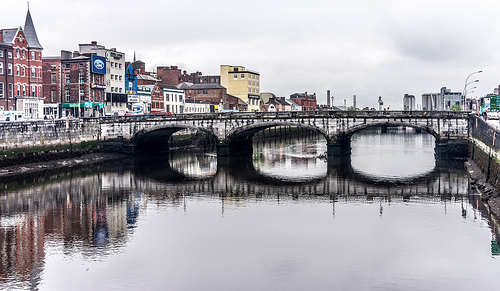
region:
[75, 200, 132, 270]
reflection in the water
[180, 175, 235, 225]
water next to the bridge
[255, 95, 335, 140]
bridge above the water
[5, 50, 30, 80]
windows on the building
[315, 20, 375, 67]
white sky above bridge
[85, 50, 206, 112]
many buildings next to bridge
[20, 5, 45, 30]
top of the tower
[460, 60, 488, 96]
lights next to bridge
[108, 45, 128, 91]
white building next to bridge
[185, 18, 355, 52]
clouds in the sky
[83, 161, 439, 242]
reflection is in water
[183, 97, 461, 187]
the bridge is over water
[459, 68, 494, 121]
the light posts is silver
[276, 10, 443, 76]
the sky is cloudy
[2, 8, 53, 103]
the buiding is brick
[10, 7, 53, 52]
the steeple is gray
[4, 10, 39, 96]
the steeple is on building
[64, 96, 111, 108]
the awning is green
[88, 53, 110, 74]
the sign is blue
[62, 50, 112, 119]
the sign is on building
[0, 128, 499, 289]
calm shiny water in the middle of a city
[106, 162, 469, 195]
reflection of a bridge in the water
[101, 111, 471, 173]
bridge spanning water flowing through a city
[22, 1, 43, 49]
pointed roof atop a red building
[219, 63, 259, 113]
tall square yellow building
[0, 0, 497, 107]
cloudy hazy sky above the city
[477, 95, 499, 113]
small green and white directional signs on a highway to the right of the bridge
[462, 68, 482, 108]
row of streetlights to the right of the bridge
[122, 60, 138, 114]
blue building to the left of the bridge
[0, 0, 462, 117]
entire range of buildings surrounding the water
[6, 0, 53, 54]
Steeple on a building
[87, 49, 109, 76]
Blue sign with oval photo inside.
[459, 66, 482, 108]
Street lights.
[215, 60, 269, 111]
Cream colored building.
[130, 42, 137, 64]
Building steeple in the distance.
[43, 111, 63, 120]
People walking.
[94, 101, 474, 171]
Bridge over a body of water.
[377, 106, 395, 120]
People crossing the bridge.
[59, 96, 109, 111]
Green awning on building.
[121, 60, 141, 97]
Blue building with brown roof.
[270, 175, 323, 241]
part of a water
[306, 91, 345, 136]
part of a bridge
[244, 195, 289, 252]
part of a water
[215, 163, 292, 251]
part of a surface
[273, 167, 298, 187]
part of a reflection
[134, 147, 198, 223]
part of a river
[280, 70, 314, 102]
part of a house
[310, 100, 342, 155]
part of a pillar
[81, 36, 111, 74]
part of a house